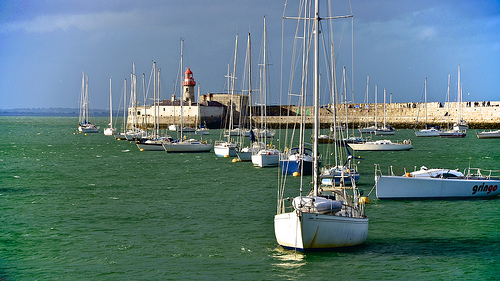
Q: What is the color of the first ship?
A: White.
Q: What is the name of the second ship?
A: Gringo.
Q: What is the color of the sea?
A: Green.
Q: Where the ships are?
A: In the sea.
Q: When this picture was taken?
A: During the day.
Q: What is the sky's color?
A: Blue.